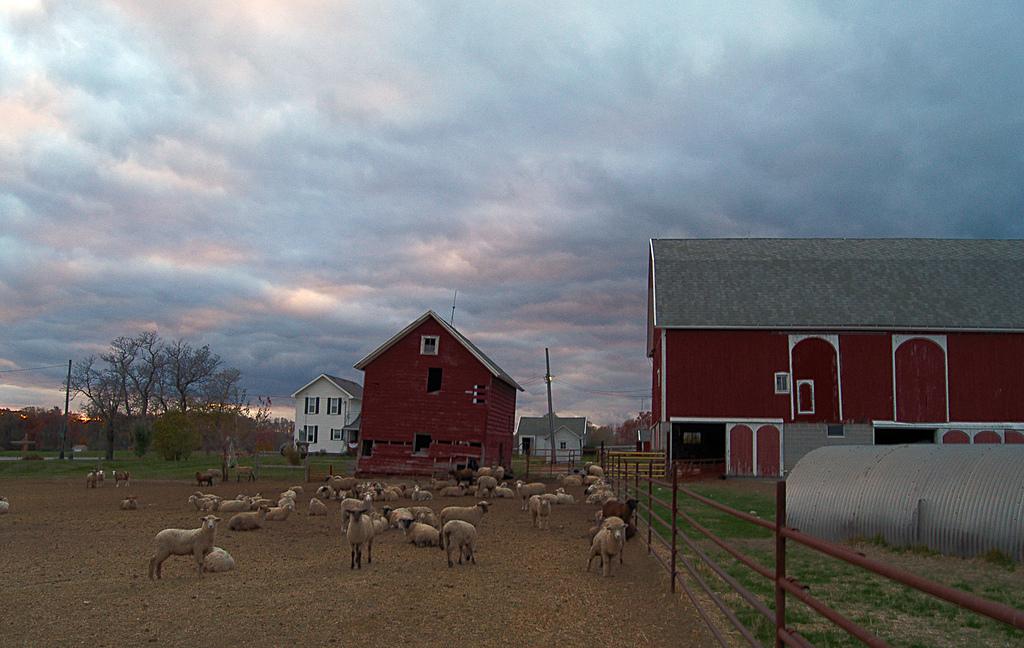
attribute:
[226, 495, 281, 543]
wool — white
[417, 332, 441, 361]
window — small, white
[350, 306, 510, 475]
building — red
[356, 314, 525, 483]
barn — tall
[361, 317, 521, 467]
barn — tall, red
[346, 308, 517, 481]
barn — very large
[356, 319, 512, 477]
barn — red, white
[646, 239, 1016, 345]
roof — long, gray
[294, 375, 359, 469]
house — large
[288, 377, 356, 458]
house — white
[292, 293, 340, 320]
portion — slightly, shining, reddish, white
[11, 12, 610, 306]
sky — slightly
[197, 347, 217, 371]
leaves — green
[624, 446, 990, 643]
fence — long, red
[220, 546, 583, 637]
side — right side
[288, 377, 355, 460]
building — painted, white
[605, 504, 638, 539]
sheep — small, brown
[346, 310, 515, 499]
building — red, broken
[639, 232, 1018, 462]
barn — large, red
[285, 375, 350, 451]
house — white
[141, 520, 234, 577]
sheep — small, brown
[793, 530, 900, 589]
pipe — long, metal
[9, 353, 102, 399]
wires — long, electrical